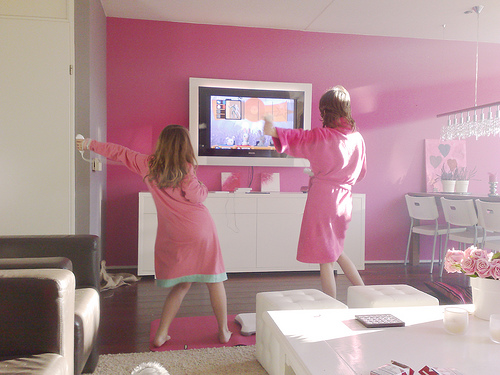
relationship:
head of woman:
[311, 81, 355, 137] [256, 76, 411, 318]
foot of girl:
[138, 312, 242, 349] [82, 101, 240, 352]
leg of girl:
[156, 233, 236, 354] [82, 101, 240, 352]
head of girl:
[149, 107, 201, 184] [82, 101, 240, 352]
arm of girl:
[67, 125, 162, 196] [82, 101, 240, 352]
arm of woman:
[253, 109, 320, 166] [256, 76, 411, 318]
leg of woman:
[301, 186, 376, 315] [256, 76, 411, 318]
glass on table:
[437, 303, 474, 341] [252, 295, 496, 372]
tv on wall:
[187, 69, 318, 168] [111, 12, 452, 274]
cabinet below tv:
[128, 179, 379, 281] [187, 69, 318, 168]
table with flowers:
[252, 295, 496, 372] [443, 242, 499, 295]